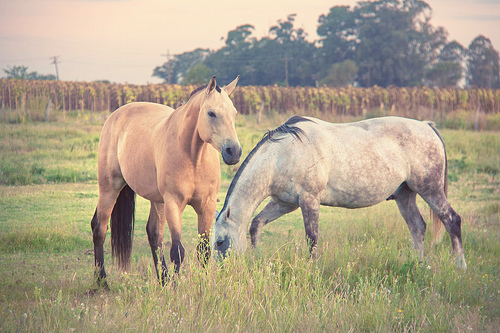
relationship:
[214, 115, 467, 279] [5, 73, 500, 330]
greyhorse in field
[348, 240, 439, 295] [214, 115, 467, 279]
grass in front of greyhorse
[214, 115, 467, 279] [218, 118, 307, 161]
greyhorse has mane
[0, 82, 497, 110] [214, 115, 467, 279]
corn behind greyhorse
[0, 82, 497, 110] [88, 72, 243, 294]
corn behind horse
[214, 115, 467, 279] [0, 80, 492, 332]
greyhorse in meadow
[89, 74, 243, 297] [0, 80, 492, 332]
horse in meadow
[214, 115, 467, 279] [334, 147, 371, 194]
greyhorse has specks